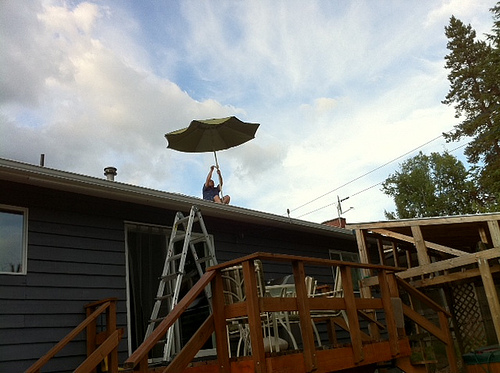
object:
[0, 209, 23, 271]
window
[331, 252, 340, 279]
window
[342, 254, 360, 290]
window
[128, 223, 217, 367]
window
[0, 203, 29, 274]
window frame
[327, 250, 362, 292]
window frame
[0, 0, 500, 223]
clouds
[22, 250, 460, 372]
deck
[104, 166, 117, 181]
vent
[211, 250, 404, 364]
railing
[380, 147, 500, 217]
leaves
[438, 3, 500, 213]
tree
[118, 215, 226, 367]
doors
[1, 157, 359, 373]
wall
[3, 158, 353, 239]
roof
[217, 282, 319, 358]
table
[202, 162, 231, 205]
man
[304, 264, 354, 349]
chair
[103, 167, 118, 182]
gutter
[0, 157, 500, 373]
building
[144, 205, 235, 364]
ladder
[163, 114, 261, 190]
umbrella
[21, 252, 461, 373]
wooden deck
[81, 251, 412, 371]
patio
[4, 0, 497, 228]
sky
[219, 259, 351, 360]
furniture